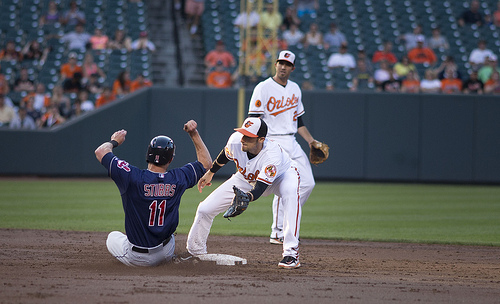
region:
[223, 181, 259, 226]
baseball glove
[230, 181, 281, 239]
baseball glove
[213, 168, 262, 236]
baseball glove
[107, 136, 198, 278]
this is a man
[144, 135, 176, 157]
this is a helmet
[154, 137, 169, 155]
the helmet is black in color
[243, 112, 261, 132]
this is a cap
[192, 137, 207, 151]
the man is light skinned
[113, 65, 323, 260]
the players are three in number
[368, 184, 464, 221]
this is grass area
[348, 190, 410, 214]
the grass is green in color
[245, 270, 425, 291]
this is the playing ground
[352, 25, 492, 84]
these are the supporters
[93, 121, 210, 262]
a baseball player on the field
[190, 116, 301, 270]
a baseball player on the field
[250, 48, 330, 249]
a baseball player on the field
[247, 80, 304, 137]
a white and orange baseball jersey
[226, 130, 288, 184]
a white and orange baseball jersey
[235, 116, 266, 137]
an orange black and white baseball hat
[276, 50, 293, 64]
an orange black and white baseball hat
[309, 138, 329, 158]
a brown baseball glove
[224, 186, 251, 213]
a black baseball glove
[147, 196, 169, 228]
a red and white number 11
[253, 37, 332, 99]
shortstop of the Orioles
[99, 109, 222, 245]
player sliding into the base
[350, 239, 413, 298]
brown dirt under players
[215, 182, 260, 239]
glove of the second baseman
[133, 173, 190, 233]
name and number on jersey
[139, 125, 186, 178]
helmet of the player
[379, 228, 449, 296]
tracks on the dirt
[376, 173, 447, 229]
green outfield grass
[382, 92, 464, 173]
wall behind the warning track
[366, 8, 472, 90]
blurry fans in stands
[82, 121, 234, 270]
The man has a blue and white uniform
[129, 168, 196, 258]
The number 11 in red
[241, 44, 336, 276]
The man is wearing a white uniform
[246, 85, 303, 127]
The lettering is in orange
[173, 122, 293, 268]
The man is leaping from the white base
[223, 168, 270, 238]
The man is wearing a brown mitt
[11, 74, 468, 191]
The wall is dark green panels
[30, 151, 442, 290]
The field is dirt and grass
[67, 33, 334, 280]
The players are on dirt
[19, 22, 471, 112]
The spectators are behind the wall